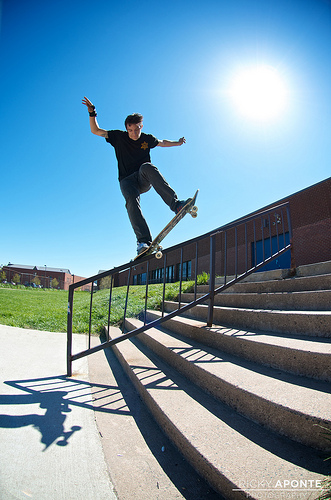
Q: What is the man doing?
A: Skateboarding.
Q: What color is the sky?
A: Blue.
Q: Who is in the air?
A: The skateboarder.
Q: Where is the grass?
A: Behind the stairs.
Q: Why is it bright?
A: The sun is shining.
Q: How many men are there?
A: One.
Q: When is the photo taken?
A: Daytime.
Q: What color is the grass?
A: Green.